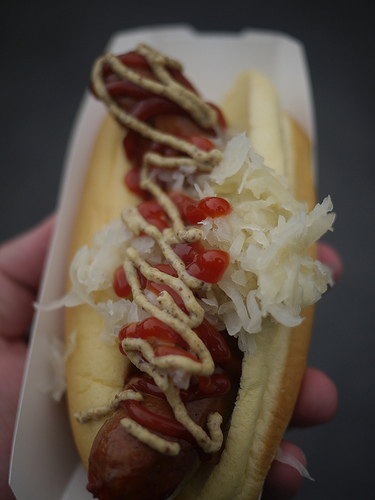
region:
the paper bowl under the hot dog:
[8, 23, 316, 498]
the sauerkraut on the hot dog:
[32, 130, 335, 403]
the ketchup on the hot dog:
[90, 52, 232, 437]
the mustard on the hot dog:
[73, 43, 223, 454]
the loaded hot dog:
[64, 44, 334, 498]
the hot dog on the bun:
[85, 42, 229, 498]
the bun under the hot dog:
[63, 71, 313, 498]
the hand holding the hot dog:
[0, 211, 342, 498]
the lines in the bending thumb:
[0, 266, 39, 342]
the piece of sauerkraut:
[275, 444, 315, 480]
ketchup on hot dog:
[117, 172, 210, 352]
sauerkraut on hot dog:
[90, 41, 223, 454]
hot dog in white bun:
[73, 92, 288, 454]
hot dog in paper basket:
[71, 62, 311, 462]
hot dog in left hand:
[103, 75, 325, 498]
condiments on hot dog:
[106, 58, 318, 480]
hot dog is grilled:
[123, 60, 283, 482]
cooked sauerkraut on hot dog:
[92, 155, 296, 349]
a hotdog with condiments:
[47, 26, 304, 466]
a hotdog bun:
[73, 58, 318, 484]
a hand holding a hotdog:
[9, 122, 344, 477]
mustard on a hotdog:
[78, 69, 248, 460]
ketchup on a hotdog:
[89, 48, 236, 459]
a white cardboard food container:
[45, 15, 303, 465]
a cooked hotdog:
[75, 50, 244, 496]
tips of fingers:
[289, 225, 349, 483]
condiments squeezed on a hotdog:
[99, 48, 235, 451]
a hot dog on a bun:
[75, 86, 292, 462]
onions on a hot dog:
[71, 122, 336, 397]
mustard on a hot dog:
[107, 96, 252, 462]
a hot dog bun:
[45, 81, 210, 428]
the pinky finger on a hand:
[273, 442, 314, 496]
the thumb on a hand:
[3, 201, 111, 319]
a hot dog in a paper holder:
[10, 42, 351, 477]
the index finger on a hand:
[291, 215, 372, 291]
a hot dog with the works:
[11, 12, 368, 498]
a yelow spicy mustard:
[113, 242, 216, 383]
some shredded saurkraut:
[245, 172, 332, 320]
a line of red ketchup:
[127, 161, 223, 226]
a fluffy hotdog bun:
[90, 128, 124, 234]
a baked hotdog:
[71, 380, 208, 498]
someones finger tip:
[309, 368, 347, 430]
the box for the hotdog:
[8, 318, 73, 498]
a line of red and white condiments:
[90, 51, 252, 492]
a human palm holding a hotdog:
[0, 210, 32, 376]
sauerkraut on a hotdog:
[65, 141, 339, 335]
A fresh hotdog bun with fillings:
[67, 73, 315, 496]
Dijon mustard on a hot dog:
[83, 38, 227, 466]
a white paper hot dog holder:
[8, 25, 318, 496]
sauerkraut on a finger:
[277, 441, 313, 482]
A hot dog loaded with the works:
[60, 39, 319, 499]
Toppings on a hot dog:
[113, 157, 307, 335]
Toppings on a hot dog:
[103, 255, 254, 392]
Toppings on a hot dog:
[113, 239, 267, 372]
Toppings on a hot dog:
[103, 270, 240, 384]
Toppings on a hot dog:
[106, 231, 276, 396]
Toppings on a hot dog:
[97, 230, 265, 378]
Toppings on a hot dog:
[102, 245, 280, 412]